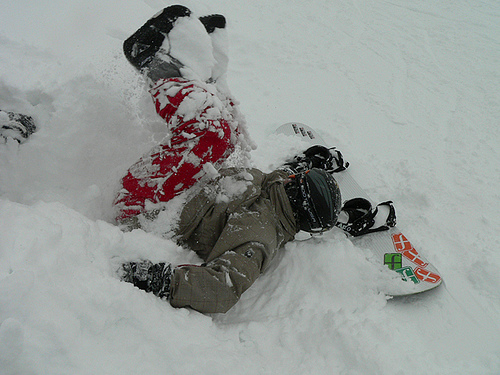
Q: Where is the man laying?
A: Snow.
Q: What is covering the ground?
A: Snow.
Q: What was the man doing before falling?
A: Snow boarding.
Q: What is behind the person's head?
A: Snow board.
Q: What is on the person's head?
A: Snow board.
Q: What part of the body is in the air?
A: Feet.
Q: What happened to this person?
A: They fell.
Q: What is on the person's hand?
A: Glove.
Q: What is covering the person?
A: Snow.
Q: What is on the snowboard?
A: Foot straps.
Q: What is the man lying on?
A: Snow.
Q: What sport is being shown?
A: Snowboarding.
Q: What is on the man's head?
A: Facemask.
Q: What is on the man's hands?
A: Gloves.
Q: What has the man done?
A: Fallen.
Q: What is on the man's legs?
A: Red pants.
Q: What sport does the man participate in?
A: Snowboarding.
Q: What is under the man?
A: Snow.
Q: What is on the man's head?
A: Helmet.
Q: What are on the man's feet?
A: Boots.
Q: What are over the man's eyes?
A: Goggles.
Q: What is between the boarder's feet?
A: Snow.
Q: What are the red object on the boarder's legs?
A: Pants.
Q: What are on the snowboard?
A: Foot straps.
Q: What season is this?
A: Winter.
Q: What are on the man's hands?
A: Gloves.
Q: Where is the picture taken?
A: A ski slope.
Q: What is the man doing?
A: Laying in the snow.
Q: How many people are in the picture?
A: One.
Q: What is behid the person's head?
A: Snowboard.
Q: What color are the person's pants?
A: Red.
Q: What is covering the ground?
A: Snow.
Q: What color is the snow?
A: White.